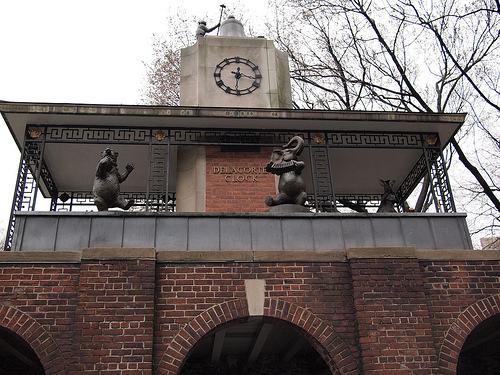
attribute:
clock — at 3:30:
[189, 37, 272, 102]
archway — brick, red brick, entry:
[161, 269, 357, 362]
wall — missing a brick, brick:
[91, 274, 123, 340]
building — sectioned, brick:
[19, 284, 499, 359]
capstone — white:
[223, 276, 283, 314]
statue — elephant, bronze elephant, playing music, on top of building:
[172, 0, 289, 44]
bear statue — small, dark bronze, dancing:
[67, 142, 145, 209]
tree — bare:
[287, 4, 499, 101]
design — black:
[52, 127, 154, 142]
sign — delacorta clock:
[208, 160, 280, 187]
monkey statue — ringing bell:
[195, 20, 208, 36]